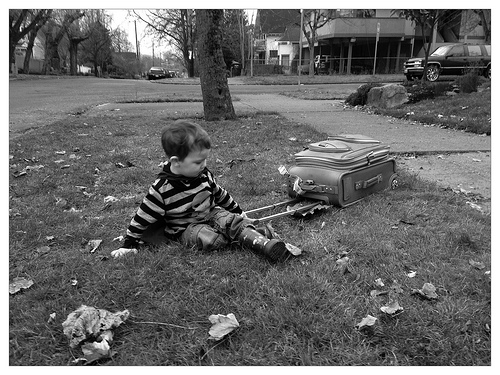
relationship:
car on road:
[402, 38, 499, 83] [94, 74, 396, 95]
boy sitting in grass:
[111, 119, 288, 263] [304, 236, 484, 346]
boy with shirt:
[111, 119, 288, 263] [113, 144, 230, 214]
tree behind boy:
[181, 20, 249, 125] [111, 119, 288, 263]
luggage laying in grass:
[237, 135, 401, 224] [9, 110, 486, 365]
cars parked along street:
[144, 67, 175, 78] [62, 75, 143, 87]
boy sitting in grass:
[111, 119, 288, 263] [9, 110, 486, 365]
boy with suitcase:
[111, 119, 288, 263] [271, 130, 403, 210]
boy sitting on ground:
[111, 119, 288, 263] [14, 76, 490, 365]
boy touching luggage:
[111, 119, 288, 263] [237, 135, 401, 224]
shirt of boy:
[118, 162, 242, 249] [111, 119, 288, 263]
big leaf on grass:
[57, 302, 131, 365] [10, 74, 488, 364]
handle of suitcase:
[237, 191, 326, 221] [229, 106, 427, 296]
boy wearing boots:
[111, 119, 288, 263] [238, 220, 295, 263]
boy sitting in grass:
[109, 118, 297, 265] [9, 110, 486, 365]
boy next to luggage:
[109, 118, 297, 265] [237, 128, 404, 224]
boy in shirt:
[111, 119, 288, 263] [118, 165, 242, 250]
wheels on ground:
[384, 170, 405, 191] [14, 76, 490, 365]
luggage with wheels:
[237, 128, 404, 224] [384, 170, 405, 191]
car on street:
[402, 38, 499, 83] [9, 75, 409, 132]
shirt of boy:
[118, 165, 242, 250] [109, 118, 297, 265]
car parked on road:
[402, 38, 499, 86] [6, 70, 403, 127]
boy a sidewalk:
[111, 119, 288, 263] [259, 92, 494, 212]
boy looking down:
[111, 119, 288, 263] [152, 234, 388, 375]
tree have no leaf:
[182, 0, 248, 126] [208, 314, 240, 342]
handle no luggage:
[358, 172, 381, 195] [240, 156, 346, 284]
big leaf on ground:
[57, 302, 131, 365] [87, 161, 467, 334]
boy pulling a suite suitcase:
[111, 119, 288, 263] [240, 120, 397, 220]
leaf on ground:
[208, 314, 240, 342] [14, 76, 490, 365]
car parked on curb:
[402, 38, 499, 83] [236, 254, 390, 375]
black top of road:
[246, 88, 485, 230] [6, 70, 403, 127]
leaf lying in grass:
[206, 308, 245, 340] [13, 254, 490, 359]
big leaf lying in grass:
[57, 302, 131, 365] [9, 110, 486, 365]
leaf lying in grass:
[408, 284, 445, 301] [239, 74, 403, 87]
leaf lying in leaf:
[408, 284, 445, 301] [356, 314, 382, 336]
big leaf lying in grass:
[57, 302, 131, 365] [15, 97, 494, 358]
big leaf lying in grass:
[57, 302, 131, 365] [174, 271, 370, 375]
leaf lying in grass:
[208, 314, 240, 342] [87, 77, 169, 114]